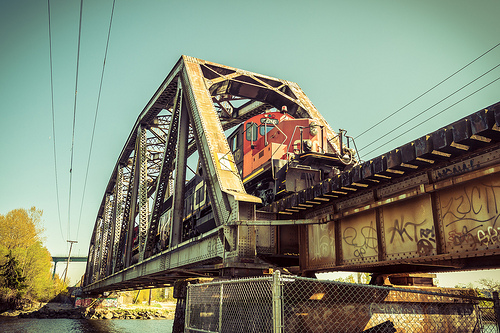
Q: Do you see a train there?
A: Yes, there is a train.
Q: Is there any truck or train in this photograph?
A: Yes, there is a train.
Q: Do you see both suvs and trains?
A: No, there is a train but no suvs.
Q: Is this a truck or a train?
A: This is a train.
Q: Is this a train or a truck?
A: This is a train.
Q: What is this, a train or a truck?
A: This is a train.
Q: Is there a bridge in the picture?
A: Yes, there is a bridge.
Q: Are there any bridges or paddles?
A: Yes, there is a bridge.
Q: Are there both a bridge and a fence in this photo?
A: Yes, there are both a bridge and a fence.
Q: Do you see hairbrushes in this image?
A: No, there are no hairbrushes.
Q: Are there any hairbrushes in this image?
A: No, there are no hairbrushes.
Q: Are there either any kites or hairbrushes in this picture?
A: No, there are no hairbrushes or kites.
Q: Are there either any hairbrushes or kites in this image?
A: No, there are no hairbrushes or kites.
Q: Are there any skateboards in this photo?
A: No, there are no skateboards.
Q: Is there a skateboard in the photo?
A: No, there are no skateboards.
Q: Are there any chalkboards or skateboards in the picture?
A: No, there are no skateboards or chalkboards.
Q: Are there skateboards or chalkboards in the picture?
A: No, there are no skateboards or chalkboards.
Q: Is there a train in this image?
A: Yes, there is a train.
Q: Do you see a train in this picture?
A: Yes, there is a train.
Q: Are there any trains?
A: Yes, there is a train.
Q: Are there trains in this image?
A: Yes, there is a train.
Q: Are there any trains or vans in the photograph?
A: Yes, there is a train.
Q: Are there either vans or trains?
A: Yes, there is a train.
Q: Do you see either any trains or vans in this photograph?
A: Yes, there is a train.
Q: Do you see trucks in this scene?
A: No, there are no trucks.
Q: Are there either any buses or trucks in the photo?
A: No, there are no trucks or buses.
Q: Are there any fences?
A: Yes, there is a fence.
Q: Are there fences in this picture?
A: Yes, there is a fence.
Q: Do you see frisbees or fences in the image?
A: Yes, there is a fence.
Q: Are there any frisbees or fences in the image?
A: Yes, there is a fence.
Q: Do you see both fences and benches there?
A: No, there is a fence but no benches.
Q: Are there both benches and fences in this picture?
A: No, there is a fence but no benches.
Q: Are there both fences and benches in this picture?
A: No, there is a fence but no benches.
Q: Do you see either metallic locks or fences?
A: Yes, there is a metal fence.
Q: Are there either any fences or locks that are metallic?
A: Yes, the fence is metallic.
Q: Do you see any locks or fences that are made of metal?
A: Yes, the fence is made of metal.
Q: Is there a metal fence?
A: Yes, there is a fence that is made of metal.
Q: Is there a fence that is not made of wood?
A: Yes, there is a fence that is made of metal.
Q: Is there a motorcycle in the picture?
A: No, there are no motorcycles.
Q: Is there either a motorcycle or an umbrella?
A: No, there are no motorcycles or umbrellas.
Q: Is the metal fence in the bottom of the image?
A: Yes, the fence is in the bottom of the image.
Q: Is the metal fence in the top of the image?
A: No, the fence is in the bottom of the image.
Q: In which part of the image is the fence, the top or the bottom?
A: The fence is in the bottom of the image.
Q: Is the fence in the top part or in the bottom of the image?
A: The fence is in the bottom of the image.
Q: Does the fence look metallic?
A: Yes, the fence is metallic.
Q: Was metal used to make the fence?
A: Yes, the fence is made of metal.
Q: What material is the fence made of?
A: The fence is made of metal.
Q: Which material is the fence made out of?
A: The fence is made of metal.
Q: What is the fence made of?
A: The fence is made of metal.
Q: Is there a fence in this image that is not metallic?
A: No, there is a fence but it is metallic.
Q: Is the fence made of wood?
A: No, the fence is made of metal.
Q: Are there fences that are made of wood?
A: No, there is a fence but it is made of metal.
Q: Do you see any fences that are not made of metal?
A: No, there is a fence but it is made of metal.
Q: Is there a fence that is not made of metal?
A: No, there is a fence but it is made of metal.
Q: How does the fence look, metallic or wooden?
A: The fence is metallic.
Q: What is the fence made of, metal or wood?
A: The fence is made of metal.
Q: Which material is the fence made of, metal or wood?
A: The fence is made of metal.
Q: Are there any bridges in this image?
A: Yes, there is a bridge.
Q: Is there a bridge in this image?
A: Yes, there is a bridge.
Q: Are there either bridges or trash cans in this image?
A: Yes, there is a bridge.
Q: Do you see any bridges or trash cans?
A: Yes, there is a bridge.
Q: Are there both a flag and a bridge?
A: No, there is a bridge but no flags.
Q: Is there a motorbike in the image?
A: No, there are no motorcycles.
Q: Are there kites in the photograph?
A: No, there are no kites.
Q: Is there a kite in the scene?
A: No, there are no kites.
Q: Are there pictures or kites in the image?
A: No, there are no kites or pictures.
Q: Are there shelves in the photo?
A: No, there are no shelves.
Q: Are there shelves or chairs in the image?
A: No, there are no shelves or chairs.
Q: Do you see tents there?
A: No, there are no tents.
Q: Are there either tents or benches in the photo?
A: No, there are no tents or benches.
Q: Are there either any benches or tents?
A: No, there are no tents or benches.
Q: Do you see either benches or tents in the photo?
A: No, there are no tents or benches.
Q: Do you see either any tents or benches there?
A: No, there are no tents or benches.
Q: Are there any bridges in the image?
A: Yes, there is a bridge.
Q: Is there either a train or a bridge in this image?
A: Yes, there is a bridge.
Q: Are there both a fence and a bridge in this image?
A: Yes, there are both a bridge and a fence.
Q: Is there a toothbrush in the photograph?
A: No, there are no toothbrushes.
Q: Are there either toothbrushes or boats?
A: No, there are no toothbrushes or boats.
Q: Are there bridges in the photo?
A: Yes, there is a bridge.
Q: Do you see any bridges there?
A: Yes, there is a bridge.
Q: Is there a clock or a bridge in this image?
A: Yes, there is a bridge.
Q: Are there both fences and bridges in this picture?
A: Yes, there are both a bridge and a fence.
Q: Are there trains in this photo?
A: Yes, there is a train.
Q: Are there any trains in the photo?
A: Yes, there is a train.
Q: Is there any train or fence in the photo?
A: Yes, there is a train.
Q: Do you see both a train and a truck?
A: No, there is a train but no trucks.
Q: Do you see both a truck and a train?
A: No, there is a train but no trucks.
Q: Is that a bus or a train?
A: That is a train.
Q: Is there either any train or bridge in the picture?
A: Yes, there is a bridge.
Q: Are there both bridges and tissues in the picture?
A: No, there is a bridge but no tissues.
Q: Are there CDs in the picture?
A: No, there are no cds.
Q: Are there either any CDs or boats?
A: No, there are no CDs or boats.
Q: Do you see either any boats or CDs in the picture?
A: No, there are no CDs or boats.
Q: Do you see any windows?
A: Yes, there is a window.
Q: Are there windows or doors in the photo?
A: Yes, there is a window.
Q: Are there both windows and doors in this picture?
A: No, there is a window but no doors.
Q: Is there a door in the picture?
A: No, there are no doors.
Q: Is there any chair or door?
A: No, there are no doors or chairs.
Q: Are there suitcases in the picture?
A: No, there are no suitcases.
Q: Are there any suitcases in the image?
A: No, there are no suitcases.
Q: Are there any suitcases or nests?
A: No, there are no suitcases or nests.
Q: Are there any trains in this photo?
A: Yes, there is a train.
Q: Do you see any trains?
A: Yes, there is a train.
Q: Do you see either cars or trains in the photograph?
A: Yes, there is a train.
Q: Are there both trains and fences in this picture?
A: Yes, there are both a train and a fence.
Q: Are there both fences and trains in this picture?
A: Yes, there are both a train and a fence.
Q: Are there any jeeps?
A: No, there are no jeeps.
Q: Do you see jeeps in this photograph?
A: No, there are no jeeps.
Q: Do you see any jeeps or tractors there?
A: No, there are no jeeps or tractors.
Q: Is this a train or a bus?
A: This is a train.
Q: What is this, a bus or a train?
A: This is a train.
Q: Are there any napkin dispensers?
A: No, there are no napkin dispensers.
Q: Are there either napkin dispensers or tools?
A: No, there are no napkin dispensers or tools.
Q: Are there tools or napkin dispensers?
A: No, there are no napkin dispensers or tools.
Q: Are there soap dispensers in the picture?
A: No, there are no soap dispensers.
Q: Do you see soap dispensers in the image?
A: No, there are no soap dispensers.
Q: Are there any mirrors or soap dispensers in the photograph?
A: No, there are no soap dispensers or mirrors.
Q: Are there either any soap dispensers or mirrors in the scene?
A: No, there are no soap dispensers or mirrors.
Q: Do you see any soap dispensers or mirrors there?
A: No, there are no soap dispensers or mirrors.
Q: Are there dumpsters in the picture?
A: No, there are no dumpsters.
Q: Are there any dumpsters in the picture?
A: No, there are no dumpsters.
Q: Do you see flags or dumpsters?
A: No, there are no dumpsters or flags.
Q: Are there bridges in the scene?
A: Yes, there is a bridge.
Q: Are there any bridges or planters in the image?
A: Yes, there is a bridge.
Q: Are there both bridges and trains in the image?
A: Yes, there are both a bridge and a train.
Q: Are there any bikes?
A: No, there are no bikes.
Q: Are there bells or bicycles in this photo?
A: No, there are no bicycles or bells.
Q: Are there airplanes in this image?
A: No, there are no airplanes.